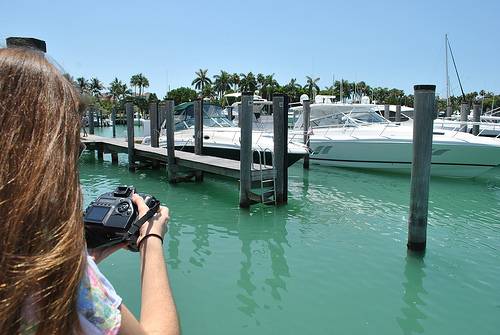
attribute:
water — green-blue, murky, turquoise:
[105, 153, 499, 333]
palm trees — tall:
[84, 67, 414, 98]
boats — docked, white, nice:
[170, 99, 494, 183]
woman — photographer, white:
[0, 44, 174, 334]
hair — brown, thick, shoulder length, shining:
[2, 48, 79, 277]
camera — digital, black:
[84, 184, 156, 236]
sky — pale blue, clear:
[8, 3, 499, 78]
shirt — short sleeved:
[27, 246, 128, 334]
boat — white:
[313, 100, 417, 162]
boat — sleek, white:
[272, 93, 497, 185]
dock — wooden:
[81, 98, 296, 220]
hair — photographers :
[12, 50, 112, 334]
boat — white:
[264, 94, 499, 179]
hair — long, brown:
[0, 47, 87, 332]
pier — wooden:
[81, 94, 315, 221]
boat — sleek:
[313, 103, 478, 183]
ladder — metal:
[250, 147, 276, 200]